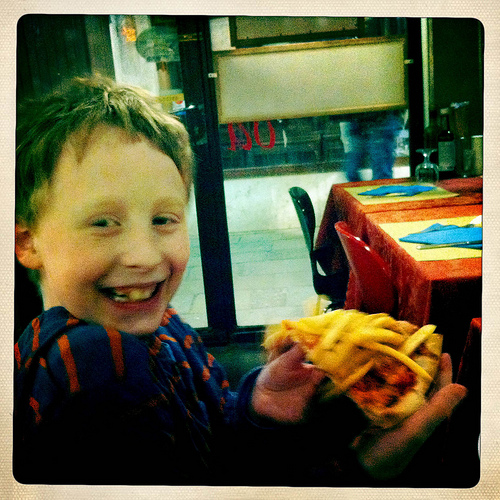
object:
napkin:
[397, 214, 483, 250]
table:
[317, 179, 483, 331]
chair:
[331, 218, 401, 317]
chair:
[288, 187, 351, 303]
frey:
[263, 315, 301, 351]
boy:
[15, 74, 470, 488]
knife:
[413, 238, 472, 252]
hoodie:
[14, 305, 382, 486]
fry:
[260, 310, 452, 430]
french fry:
[350, 325, 407, 348]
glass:
[415, 142, 440, 184]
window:
[106, 14, 441, 335]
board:
[202, 15, 430, 127]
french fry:
[313, 351, 373, 385]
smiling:
[97, 272, 171, 320]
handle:
[186, 103, 207, 144]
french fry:
[360, 334, 437, 384]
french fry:
[397, 321, 439, 359]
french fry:
[321, 358, 375, 398]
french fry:
[316, 313, 362, 351]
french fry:
[285, 317, 329, 338]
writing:
[225, 122, 275, 152]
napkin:
[357, 182, 440, 198]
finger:
[362, 384, 471, 473]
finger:
[274, 341, 324, 367]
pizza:
[260, 307, 442, 427]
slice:
[255, 306, 448, 434]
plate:
[383, 213, 486, 265]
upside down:
[414, 146, 439, 185]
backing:
[285, 186, 333, 296]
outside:
[206, 18, 429, 332]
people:
[331, 109, 403, 183]